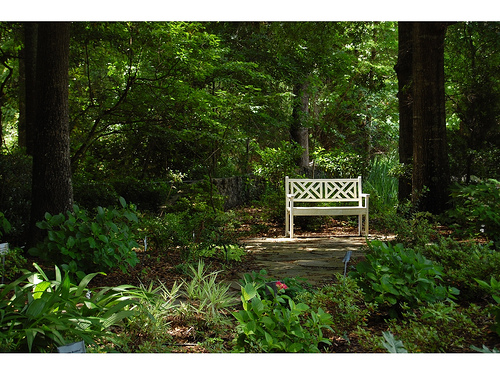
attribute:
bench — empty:
[284, 175, 370, 239]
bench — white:
[269, 154, 401, 241]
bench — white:
[258, 153, 463, 330]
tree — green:
[16, 24, 228, 240]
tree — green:
[237, 20, 341, 173]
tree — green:
[397, 23, 453, 218]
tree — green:
[365, 23, 377, 173]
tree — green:
[453, 25, 497, 167]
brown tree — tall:
[387, 23, 455, 220]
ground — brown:
[260, 255, 315, 282]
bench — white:
[259, 171, 429, 269]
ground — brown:
[11, 207, 496, 339]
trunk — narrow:
[411, 19, 448, 221]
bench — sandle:
[256, 164, 392, 251]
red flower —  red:
[272, 271, 300, 298]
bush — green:
[36, 185, 183, 270]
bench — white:
[248, 167, 406, 248]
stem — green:
[341, 259, 351, 274]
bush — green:
[174, 262, 226, 297]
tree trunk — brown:
[14, 46, 76, 208]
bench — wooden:
[277, 172, 369, 233]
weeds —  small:
[323, 270, 363, 331]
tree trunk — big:
[390, 22, 458, 223]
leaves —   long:
[416, 234, 474, 349]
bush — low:
[232, 268, 335, 354]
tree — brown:
[25, 19, 75, 250]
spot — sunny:
[236, 229, 396, 255]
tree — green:
[403, 23, 448, 216]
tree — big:
[75, 70, 281, 204]